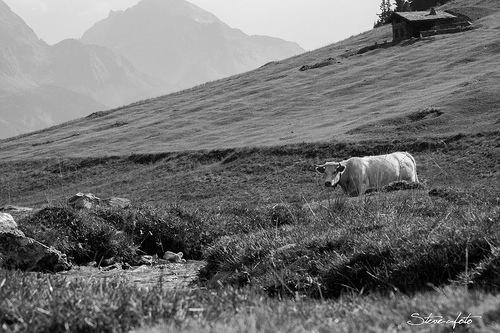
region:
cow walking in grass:
[312, 147, 425, 202]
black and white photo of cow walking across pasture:
[3, 3, 498, 325]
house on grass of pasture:
[382, 5, 481, 45]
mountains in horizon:
[2, 1, 305, 148]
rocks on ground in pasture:
[2, 207, 73, 276]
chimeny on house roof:
[422, 3, 442, 17]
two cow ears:
[309, 158, 346, 173]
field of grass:
[8, 0, 498, 260]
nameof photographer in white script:
[395, 302, 487, 332]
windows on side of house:
[390, 25, 407, 40]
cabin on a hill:
[384, 1, 477, 56]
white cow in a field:
[309, 142, 429, 202]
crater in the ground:
[353, 100, 451, 142]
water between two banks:
[48, 221, 223, 297]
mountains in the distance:
[0, 1, 305, 102]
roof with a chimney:
[394, 5, 459, 21]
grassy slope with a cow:
[242, 135, 493, 296]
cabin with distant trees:
[369, 0, 477, 51]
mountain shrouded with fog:
[61, 0, 284, 109]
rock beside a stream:
[0, 214, 98, 280]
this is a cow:
[309, 133, 431, 215]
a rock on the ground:
[7, 229, 72, 296]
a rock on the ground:
[61, 178, 101, 224]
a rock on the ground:
[107, 184, 139, 226]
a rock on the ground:
[0, 210, 31, 246]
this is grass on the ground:
[210, 240, 325, 310]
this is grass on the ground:
[329, 227, 384, 287]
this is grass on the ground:
[176, 199, 238, 240]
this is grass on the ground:
[215, 268, 292, 319]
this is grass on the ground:
[416, 186, 473, 299]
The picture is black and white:
[2, 0, 499, 332]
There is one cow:
[316, 148, 425, 190]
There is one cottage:
[388, 9, 473, 36]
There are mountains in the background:
[0, 0, 310, 100]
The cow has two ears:
[313, 163, 350, 172]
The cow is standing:
[317, 155, 433, 193]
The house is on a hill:
[124, 8, 491, 99]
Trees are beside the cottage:
[375, 0, 390, 32]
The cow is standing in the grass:
[308, 148, 438, 197]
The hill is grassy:
[48, 52, 498, 147]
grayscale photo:
[0, 0, 498, 331]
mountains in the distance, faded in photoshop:
[0, 0, 326, 147]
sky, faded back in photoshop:
[0, 0, 395, 65]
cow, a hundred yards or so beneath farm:
[301, 0, 491, 205]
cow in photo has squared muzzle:
[317, 175, 332, 187]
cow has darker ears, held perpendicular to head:
[309, 162, 351, 177]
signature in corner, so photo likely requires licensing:
[402, 303, 485, 330]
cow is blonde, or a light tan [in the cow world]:
[308, 146, 430, 204]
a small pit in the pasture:
[339, 103, 448, 141]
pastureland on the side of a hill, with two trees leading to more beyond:
[0, 0, 497, 217]